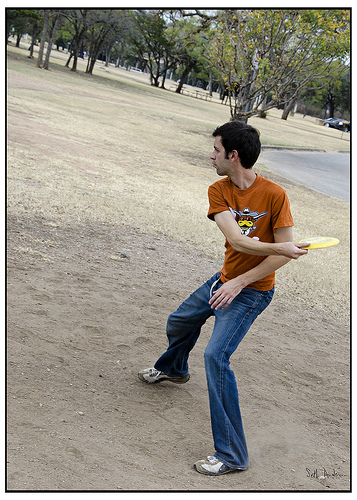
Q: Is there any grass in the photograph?
A: Yes, there is grass.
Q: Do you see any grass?
A: Yes, there is grass.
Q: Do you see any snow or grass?
A: Yes, there is grass.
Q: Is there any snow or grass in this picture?
A: Yes, there is grass.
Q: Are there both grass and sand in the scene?
A: Yes, there are both grass and sand.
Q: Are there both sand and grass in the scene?
A: Yes, there are both grass and sand.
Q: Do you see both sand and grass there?
A: Yes, there are both grass and sand.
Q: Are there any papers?
A: No, there are no papers.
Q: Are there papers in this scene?
A: No, there are no papers.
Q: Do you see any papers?
A: No, there are no papers.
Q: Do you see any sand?
A: Yes, there is sand.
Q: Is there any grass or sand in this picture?
A: Yes, there is sand.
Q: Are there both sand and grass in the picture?
A: Yes, there are both sand and grass.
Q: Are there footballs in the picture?
A: No, there are no footballs.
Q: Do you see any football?
A: No, there are no footballs.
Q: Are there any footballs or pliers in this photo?
A: No, there are no footballs or pliers.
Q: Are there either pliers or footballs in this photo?
A: No, there are no footballs or pliers.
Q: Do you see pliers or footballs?
A: No, there are no footballs or pliers.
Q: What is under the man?
A: The sand is under the man.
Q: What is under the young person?
A: The sand is under the man.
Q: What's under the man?
A: The sand is under the man.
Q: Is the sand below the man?
A: Yes, the sand is below the man.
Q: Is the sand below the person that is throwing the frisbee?
A: Yes, the sand is below the man.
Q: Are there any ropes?
A: No, there are no ropes.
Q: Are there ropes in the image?
A: No, there are no ropes.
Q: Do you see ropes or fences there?
A: No, there are no ropes or fences.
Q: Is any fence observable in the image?
A: No, there are no fences.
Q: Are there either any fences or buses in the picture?
A: No, there are no fences or buses.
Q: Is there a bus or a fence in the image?
A: No, there are no fences or buses.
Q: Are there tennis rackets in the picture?
A: No, there are no tennis rackets.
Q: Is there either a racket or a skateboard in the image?
A: No, there are no rackets or skateboards.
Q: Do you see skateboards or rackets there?
A: No, there are no rackets or skateboards.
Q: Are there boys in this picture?
A: No, there are no boys.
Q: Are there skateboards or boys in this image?
A: No, there are no boys or skateboards.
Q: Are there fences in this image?
A: No, there are no fences.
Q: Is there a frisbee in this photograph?
A: Yes, there is a frisbee.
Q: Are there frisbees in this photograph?
A: Yes, there is a frisbee.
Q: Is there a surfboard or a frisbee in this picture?
A: Yes, there is a frisbee.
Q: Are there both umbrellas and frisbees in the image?
A: No, there is a frisbee but no umbrellas.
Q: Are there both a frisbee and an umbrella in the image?
A: No, there is a frisbee but no umbrellas.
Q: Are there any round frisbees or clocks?
A: Yes, there is a round frisbee.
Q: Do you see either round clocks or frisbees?
A: Yes, there is a round frisbee.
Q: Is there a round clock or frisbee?
A: Yes, there is a round frisbee.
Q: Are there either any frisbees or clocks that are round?
A: Yes, the frisbee is round.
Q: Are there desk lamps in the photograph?
A: No, there are no desk lamps.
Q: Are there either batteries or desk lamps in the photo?
A: No, there are no desk lamps or batteries.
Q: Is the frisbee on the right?
A: Yes, the frisbee is on the right of the image.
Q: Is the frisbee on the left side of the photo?
A: No, the frisbee is on the right of the image.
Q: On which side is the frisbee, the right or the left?
A: The frisbee is on the right of the image.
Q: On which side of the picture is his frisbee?
A: The frisbee is on the right of the image.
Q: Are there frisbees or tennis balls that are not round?
A: No, there is a frisbee but it is round.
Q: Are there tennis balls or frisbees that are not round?
A: No, there is a frisbee but it is round.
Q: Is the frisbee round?
A: Yes, the frisbee is round.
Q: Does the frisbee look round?
A: Yes, the frisbee is round.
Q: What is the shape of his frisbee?
A: The frisbee is round.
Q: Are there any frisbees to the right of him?
A: Yes, there is a frisbee to the right of the man.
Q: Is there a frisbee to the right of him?
A: Yes, there is a frisbee to the right of the man.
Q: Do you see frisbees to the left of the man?
A: No, the frisbee is to the right of the man.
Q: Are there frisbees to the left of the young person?
A: No, the frisbee is to the right of the man.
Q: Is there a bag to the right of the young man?
A: No, there is a frisbee to the right of the man.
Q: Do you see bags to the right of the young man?
A: No, there is a frisbee to the right of the man.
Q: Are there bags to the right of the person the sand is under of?
A: No, there is a frisbee to the right of the man.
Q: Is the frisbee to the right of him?
A: Yes, the frisbee is to the right of a man.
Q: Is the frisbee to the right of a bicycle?
A: No, the frisbee is to the right of a man.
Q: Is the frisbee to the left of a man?
A: No, the frisbee is to the right of a man.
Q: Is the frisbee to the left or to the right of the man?
A: The frisbee is to the right of the man.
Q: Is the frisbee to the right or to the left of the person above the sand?
A: The frisbee is to the right of the man.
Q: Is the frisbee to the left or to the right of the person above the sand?
A: The frisbee is to the right of the man.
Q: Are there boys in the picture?
A: No, there are no boys.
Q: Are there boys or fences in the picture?
A: No, there are no boys or fences.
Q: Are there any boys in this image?
A: No, there are no boys.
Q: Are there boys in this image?
A: No, there are no boys.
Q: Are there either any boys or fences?
A: No, there are no boys or fences.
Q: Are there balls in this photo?
A: No, there are no balls.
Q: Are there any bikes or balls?
A: No, there are no balls or bikes.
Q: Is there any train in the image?
A: No, there are no trains.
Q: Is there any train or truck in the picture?
A: No, there are no trains or trucks.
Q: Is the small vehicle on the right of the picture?
A: Yes, the car is on the right of the image.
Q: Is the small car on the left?
A: No, the car is on the right of the image.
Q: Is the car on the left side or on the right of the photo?
A: The car is on the right of the image.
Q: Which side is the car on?
A: The car is on the right of the image.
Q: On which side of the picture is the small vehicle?
A: The car is on the right of the image.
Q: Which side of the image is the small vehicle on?
A: The car is on the right of the image.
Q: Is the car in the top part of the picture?
A: Yes, the car is in the top of the image.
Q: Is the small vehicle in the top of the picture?
A: Yes, the car is in the top of the image.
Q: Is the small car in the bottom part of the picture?
A: No, the car is in the top of the image.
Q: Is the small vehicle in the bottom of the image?
A: No, the car is in the top of the image.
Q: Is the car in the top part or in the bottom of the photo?
A: The car is in the top of the image.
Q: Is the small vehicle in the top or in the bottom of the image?
A: The car is in the top of the image.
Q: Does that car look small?
A: Yes, the car is small.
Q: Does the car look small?
A: Yes, the car is small.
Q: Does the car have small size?
A: Yes, the car is small.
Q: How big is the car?
A: The car is small.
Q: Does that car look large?
A: No, the car is small.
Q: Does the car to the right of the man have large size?
A: No, the car is small.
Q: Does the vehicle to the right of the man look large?
A: No, the car is small.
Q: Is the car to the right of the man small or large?
A: The car is small.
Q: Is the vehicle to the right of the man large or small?
A: The car is small.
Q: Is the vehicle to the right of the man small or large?
A: The car is small.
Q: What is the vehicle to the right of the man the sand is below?
A: The vehicle is a car.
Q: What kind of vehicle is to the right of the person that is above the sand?
A: The vehicle is a car.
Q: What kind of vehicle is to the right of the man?
A: The vehicle is a car.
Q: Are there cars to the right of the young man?
A: Yes, there is a car to the right of the man.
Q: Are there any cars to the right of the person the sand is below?
A: Yes, there is a car to the right of the man.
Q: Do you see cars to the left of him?
A: No, the car is to the right of the man.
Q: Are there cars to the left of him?
A: No, the car is to the right of the man.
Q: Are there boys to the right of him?
A: No, there is a car to the right of the man.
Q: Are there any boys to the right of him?
A: No, there is a car to the right of the man.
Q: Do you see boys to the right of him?
A: No, there is a car to the right of the man.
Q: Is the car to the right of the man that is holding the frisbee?
A: Yes, the car is to the right of the man.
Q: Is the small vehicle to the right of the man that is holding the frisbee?
A: Yes, the car is to the right of the man.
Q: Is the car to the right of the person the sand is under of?
A: Yes, the car is to the right of the man.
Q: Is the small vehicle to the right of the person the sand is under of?
A: Yes, the car is to the right of the man.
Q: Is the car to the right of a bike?
A: No, the car is to the right of the man.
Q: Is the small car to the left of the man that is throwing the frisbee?
A: No, the car is to the right of the man.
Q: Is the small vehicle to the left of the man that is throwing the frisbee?
A: No, the car is to the right of the man.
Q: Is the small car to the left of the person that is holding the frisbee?
A: No, the car is to the right of the man.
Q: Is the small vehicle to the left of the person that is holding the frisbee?
A: No, the car is to the right of the man.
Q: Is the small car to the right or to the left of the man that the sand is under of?
A: The car is to the right of the man.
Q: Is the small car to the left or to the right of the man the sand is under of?
A: The car is to the right of the man.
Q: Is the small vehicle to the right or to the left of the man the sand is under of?
A: The car is to the right of the man.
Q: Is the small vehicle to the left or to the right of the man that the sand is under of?
A: The car is to the right of the man.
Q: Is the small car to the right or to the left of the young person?
A: The car is to the right of the man.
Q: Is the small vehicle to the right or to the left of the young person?
A: The car is to the right of the man.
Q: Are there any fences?
A: No, there are no fences.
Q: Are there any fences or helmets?
A: No, there are no fences or helmets.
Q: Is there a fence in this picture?
A: No, there are no fences.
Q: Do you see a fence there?
A: No, there are no fences.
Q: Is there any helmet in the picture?
A: No, there are no helmets.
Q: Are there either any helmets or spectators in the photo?
A: No, there are no helmets or spectators.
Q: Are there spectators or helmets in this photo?
A: No, there are no helmets or spectators.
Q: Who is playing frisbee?
A: The man is playing frisbee.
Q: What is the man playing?
A: The man is playing frisbee.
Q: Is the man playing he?
A: Yes, the man is playing frisbee.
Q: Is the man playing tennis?
A: No, the man is playing frisbee.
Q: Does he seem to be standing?
A: Yes, the man is standing.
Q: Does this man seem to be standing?
A: Yes, the man is standing.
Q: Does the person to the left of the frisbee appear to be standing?
A: Yes, the man is standing.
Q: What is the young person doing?
A: The man is standing.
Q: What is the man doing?
A: The man is standing.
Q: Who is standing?
A: The man is standing.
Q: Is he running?
A: No, the man is standing.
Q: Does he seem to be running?
A: No, the man is standing.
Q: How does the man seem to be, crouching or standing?
A: The man is standing.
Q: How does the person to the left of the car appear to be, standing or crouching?
A: The man is standing.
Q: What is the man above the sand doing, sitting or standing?
A: The man is standing.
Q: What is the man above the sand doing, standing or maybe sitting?
A: The man is standing.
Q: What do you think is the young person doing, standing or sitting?
A: The man is standing.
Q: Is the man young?
A: Yes, the man is young.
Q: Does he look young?
A: Yes, the man is young.